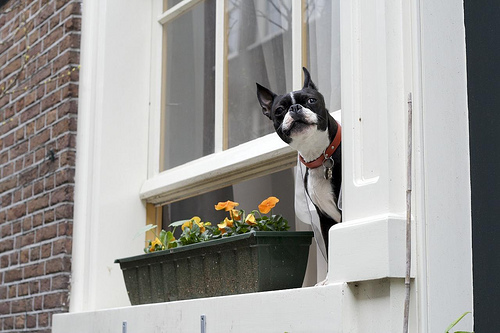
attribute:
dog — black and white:
[255, 64, 342, 254]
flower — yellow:
[148, 194, 280, 249]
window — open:
[135, 159, 332, 273]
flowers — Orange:
[257, 194, 281, 215]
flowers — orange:
[142, 194, 291, 256]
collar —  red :
[298, 124, 345, 171]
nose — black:
[284, 100, 300, 117]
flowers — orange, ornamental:
[165, 183, 379, 241]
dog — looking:
[246, 65, 376, 290]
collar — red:
[298, 128, 342, 168]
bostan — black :
[241, 61, 393, 234]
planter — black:
[113, 224, 313, 294]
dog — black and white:
[261, 71, 401, 293]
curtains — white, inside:
[230, 4, 343, 286]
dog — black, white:
[247, 60, 347, 280]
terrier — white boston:
[256, 72, 344, 232]